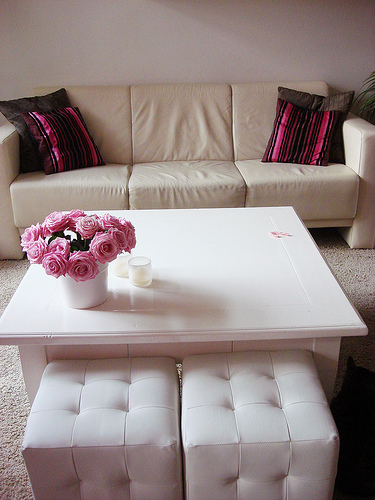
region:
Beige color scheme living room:
[26, 98, 346, 415]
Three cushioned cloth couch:
[24, 86, 370, 218]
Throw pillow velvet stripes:
[25, 110, 110, 176]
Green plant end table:
[349, 53, 374, 117]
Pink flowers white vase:
[22, 212, 140, 309]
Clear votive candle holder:
[122, 255, 162, 289]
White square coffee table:
[24, 207, 362, 354]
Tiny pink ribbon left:
[264, 219, 297, 246]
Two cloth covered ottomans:
[19, 352, 349, 497]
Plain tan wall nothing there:
[47, 6, 351, 82]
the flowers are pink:
[48, 212, 126, 265]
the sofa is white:
[53, 360, 167, 461]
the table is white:
[26, 218, 342, 320]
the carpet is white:
[343, 263, 373, 304]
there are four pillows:
[9, 87, 337, 156]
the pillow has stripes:
[274, 103, 338, 166]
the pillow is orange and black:
[274, 105, 329, 160]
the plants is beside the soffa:
[356, 72, 374, 118]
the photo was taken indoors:
[10, 190, 360, 468]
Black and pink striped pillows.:
[259, 94, 340, 167]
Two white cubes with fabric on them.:
[22, 347, 341, 498]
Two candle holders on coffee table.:
[110, 248, 152, 287]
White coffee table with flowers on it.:
[1, 204, 367, 406]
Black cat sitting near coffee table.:
[328, 355, 373, 498]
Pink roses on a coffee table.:
[64, 250, 98, 283]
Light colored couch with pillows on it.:
[2, 79, 374, 260]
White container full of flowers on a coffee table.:
[20, 210, 137, 309]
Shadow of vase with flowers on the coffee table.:
[94, 287, 223, 318]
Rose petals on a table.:
[269, 228, 290, 237]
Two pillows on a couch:
[207, 84, 373, 248]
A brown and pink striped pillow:
[258, 94, 350, 172]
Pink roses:
[15, 203, 142, 283]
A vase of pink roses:
[16, 199, 137, 315]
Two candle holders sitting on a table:
[111, 248, 159, 294]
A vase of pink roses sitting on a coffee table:
[9, 196, 217, 405]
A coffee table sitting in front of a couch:
[151, 206, 371, 405]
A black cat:
[292, 345, 374, 499]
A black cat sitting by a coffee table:
[203, 209, 373, 496]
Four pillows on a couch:
[1, 79, 373, 202]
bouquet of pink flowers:
[22, 205, 142, 291]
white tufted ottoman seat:
[31, 363, 160, 476]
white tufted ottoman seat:
[186, 354, 327, 469]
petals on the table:
[249, 219, 313, 252]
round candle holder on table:
[116, 252, 173, 287]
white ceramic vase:
[39, 275, 138, 300]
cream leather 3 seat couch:
[40, 79, 370, 184]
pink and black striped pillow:
[12, 119, 129, 176]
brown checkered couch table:
[12, 90, 56, 113]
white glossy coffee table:
[35, 207, 356, 370]